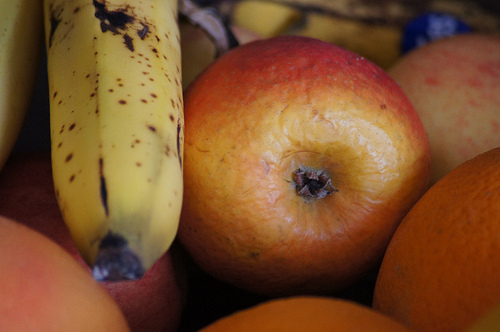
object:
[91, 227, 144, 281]
end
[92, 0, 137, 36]
bruise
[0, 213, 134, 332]
skin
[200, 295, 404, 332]
orange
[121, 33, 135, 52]
spot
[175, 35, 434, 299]
apple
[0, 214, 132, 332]
fruit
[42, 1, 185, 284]
banana